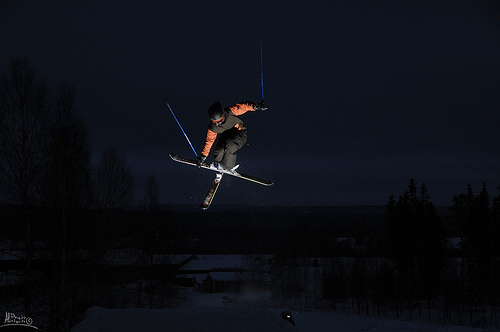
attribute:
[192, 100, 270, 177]
skier — lit, performing, snow, skiing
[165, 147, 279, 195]
ski — crossed, black, long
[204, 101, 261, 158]
jacket — black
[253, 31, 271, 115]
pole — long, blue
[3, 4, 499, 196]
sky — dark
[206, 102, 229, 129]
helmet — black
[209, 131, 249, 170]
pants — black